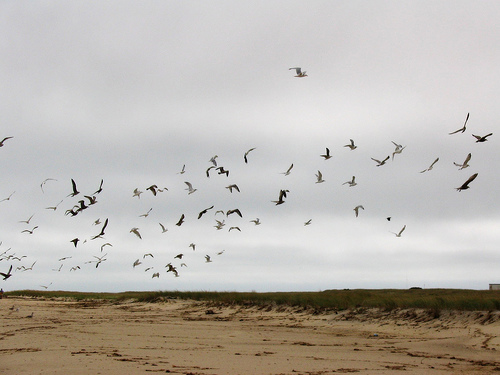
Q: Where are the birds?
A: In the sky.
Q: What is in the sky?
A: Birds.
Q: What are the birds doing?
A: Flying.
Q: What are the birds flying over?
A: The beach.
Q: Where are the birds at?
A: The beach.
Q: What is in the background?
A: Grass.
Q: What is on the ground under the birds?
A: Sand.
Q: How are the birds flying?
A: In a flock.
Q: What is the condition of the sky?
A: Overcast.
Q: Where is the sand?
A: Under the birds.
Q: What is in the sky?
A: Clouds.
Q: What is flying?
A: Birds.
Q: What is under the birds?
A: Sand.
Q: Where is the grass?
A: Behind the sand.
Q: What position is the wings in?
A: Outstretched.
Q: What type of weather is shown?
A: Cloudy.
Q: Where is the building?
A: Back on the right side.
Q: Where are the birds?
A: In air.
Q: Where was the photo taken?
A: Beach.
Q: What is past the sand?
A: Grass.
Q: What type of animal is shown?
A: Bird.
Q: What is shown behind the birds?
A: Clouds.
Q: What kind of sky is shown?
A: Overcast.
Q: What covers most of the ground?
A: Sand.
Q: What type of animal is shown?
A: Seagull.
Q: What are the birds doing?
A: Flying.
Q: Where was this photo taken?
A: Beach.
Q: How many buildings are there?
A: One.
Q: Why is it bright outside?
A: Daytime.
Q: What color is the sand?
A: Brown.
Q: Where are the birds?
A: Sky.